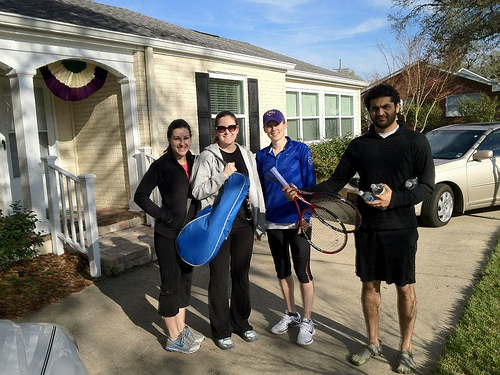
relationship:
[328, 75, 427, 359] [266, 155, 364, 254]
man holds rackets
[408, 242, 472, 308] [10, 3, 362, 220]
driveway near house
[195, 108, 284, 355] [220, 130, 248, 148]
woman has sunglasses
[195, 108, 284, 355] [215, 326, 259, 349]
woman wears shoes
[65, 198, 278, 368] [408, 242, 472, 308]
shadows on driveway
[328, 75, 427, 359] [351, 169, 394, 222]
man holds bottles